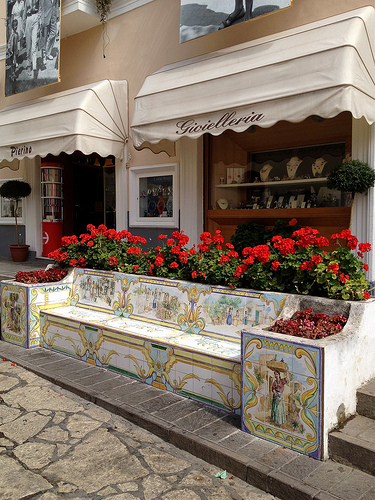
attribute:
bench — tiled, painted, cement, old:
[0, 269, 373, 462]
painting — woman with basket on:
[244, 337, 324, 459]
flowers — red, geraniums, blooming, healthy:
[46, 222, 371, 303]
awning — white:
[130, 7, 373, 156]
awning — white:
[2, 81, 129, 166]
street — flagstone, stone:
[0, 355, 279, 499]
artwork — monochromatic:
[7, 1, 63, 102]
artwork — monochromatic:
[179, 1, 291, 42]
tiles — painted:
[2, 270, 325, 462]